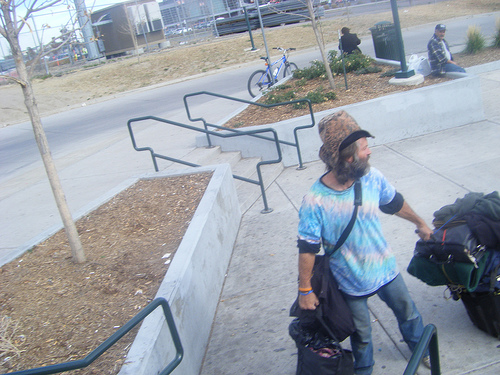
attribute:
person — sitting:
[330, 24, 371, 66]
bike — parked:
[237, 46, 306, 99]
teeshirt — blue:
[300, 178, 398, 307]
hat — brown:
[309, 113, 371, 167]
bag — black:
[275, 266, 353, 352]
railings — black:
[125, 115, 285, 208]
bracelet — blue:
[295, 291, 316, 298]